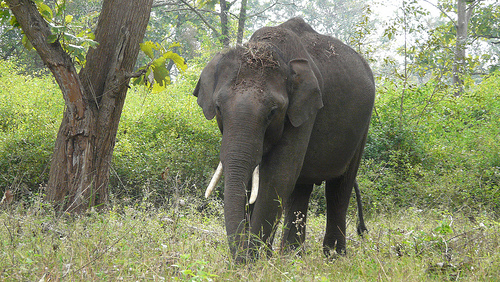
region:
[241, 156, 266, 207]
elephant trunk is ivory and stout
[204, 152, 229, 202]
elephant trunk is ivory and stout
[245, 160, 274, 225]
elephant trunk is ivory and stout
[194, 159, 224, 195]
elephant trunk is ivory and stout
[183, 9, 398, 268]
Gray Elephant walking in grass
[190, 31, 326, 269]
Gray elephant with white tusks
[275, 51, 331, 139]
Left ear of gray elephant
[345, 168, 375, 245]
Tail of gray elephant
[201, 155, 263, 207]
White tusks on gray elephant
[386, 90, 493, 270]
Wild grass and trees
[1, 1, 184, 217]
Trunk and branch of tree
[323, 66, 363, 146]
Gray side of elephant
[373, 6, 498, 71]
Trees and sky in the background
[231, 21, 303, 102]
Debris sitting on top of elephant's head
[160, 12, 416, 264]
elephant is large and grey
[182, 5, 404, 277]
The animal in the photo is a elephant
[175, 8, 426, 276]
Elephant is dark gray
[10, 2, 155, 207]
Large tree is in the background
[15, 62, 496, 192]
Green bushes is in the background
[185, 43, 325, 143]
Elephant's ears are flat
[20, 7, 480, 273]
Photo was taken in the daytime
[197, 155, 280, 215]
Elephant's tusk are white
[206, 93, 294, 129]
Elephant's eyes are black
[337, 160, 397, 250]
Elephant's tail is long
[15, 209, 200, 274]
Plants on the ground are dried out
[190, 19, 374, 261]
The picture has an elephant in it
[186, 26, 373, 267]
The elephant is grey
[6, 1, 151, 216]
The picture has a tree in it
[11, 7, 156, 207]
The tree trunk is brown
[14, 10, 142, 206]
The tree is made out of bark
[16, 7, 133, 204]
The tree is brown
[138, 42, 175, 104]
The tree has leaves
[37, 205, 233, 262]
The ground is covered in grass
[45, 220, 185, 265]
The grass is green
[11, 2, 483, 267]
The picture has multiple colors in it